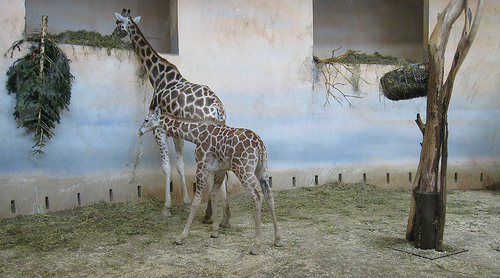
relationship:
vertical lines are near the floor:
[8, 168, 479, 217] [0, 190, 500, 278]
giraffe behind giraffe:
[137, 100, 287, 255] [110, 7, 233, 228]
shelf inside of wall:
[22, 22, 184, 62] [5, 11, 497, 200]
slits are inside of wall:
[8, 149, 498, 213] [2, 7, 490, 230]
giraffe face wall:
[110, 7, 233, 228] [1, 3, 306, 195]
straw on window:
[312, 50, 384, 108] [312, 6, 430, 66]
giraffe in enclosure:
[110, 7, 233, 228] [2, 1, 494, 275]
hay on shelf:
[28, 28, 137, 56] [21, 8, 181, 60]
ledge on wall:
[313, 34, 423, 68] [272, 4, 499, 187]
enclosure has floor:
[2, 1, 494, 275] [33, 194, 498, 274]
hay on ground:
[68, 243, 122, 263] [53, 215, 143, 264]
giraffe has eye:
[137, 100, 287, 255] [146, 119, 153, 124]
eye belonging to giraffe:
[142, 117, 150, 123] [137, 100, 287, 255]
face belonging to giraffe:
[137, 110, 156, 133] [137, 100, 287, 255]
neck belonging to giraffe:
[126, 17, 178, 85] [110, 7, 233, 228]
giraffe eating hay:
[110, 7, 233, 228] [26, 27, 139, 61]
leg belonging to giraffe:
[153, 128, 172, 218] [110, 7, 233, 228]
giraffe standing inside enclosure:
[137, 100, 287, 255] [0, 1, 499, 277]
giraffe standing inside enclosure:
[110, 7, 233, 228] [0, 1, 499, 277]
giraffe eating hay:
[110, 7, 233, 228] [28, 28, 137, 56]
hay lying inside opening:
[28, 28, 137, 56] [24, 1, 177, 55]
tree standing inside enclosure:
[402, 4, 482, 247] [0, 1, 499, 277]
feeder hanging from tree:
[378, 68, 428, 102] [402, 4, 482, 247]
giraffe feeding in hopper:
[110, 7, 233, 228] [24, 0, 178, 54]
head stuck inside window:
[107, 6, 132, 41] [23, 0, 178, 55]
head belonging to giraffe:
[107, 6, 132, 41] [110, 7, 233, 228]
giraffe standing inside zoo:
[110, 7, 233, 228] [2, 0, 484, 274]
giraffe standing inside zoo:
[137, 100, 287, 255] [2, 0, 484, 274]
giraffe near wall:
[137, 100, 287, 255] [75, 55, 138, 195]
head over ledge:
[111, 7, 142, 40] [58, 32, 158, 70]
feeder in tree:
[378, 65, 429, 98] [389, 2, 481, 261]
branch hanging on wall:
[4, 9, 77, 161] [79, 49, 128, 194]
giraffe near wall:
[137, 100, 287, 255] [218, 20, 297, 134]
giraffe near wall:
[104, 6, 245, 242] [218, 20, 297, 134]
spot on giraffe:
[242, 131, 253, 152] [130, 96, 290, 248]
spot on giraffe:
[231, 144, 248, 160] [116, 104, 290, 253]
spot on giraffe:
[226, 150, 241, 170] [137, 100, 287, 255]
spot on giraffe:
[242, 161, 252, 179] [125, 98, 290, 258]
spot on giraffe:
[168, 117, 179, 131] [122, 103, 278, 243]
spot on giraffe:
[188, 118, 196, 133] [137, 100, 287, 255]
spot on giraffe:
[194, 90, 210, 110] [109, 3, 237, 242]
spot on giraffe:
[176, 85, 186, 105] [104, 6, 245, 242]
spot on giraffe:
[147, 62, 159, 81] [110, 7, 233, 228]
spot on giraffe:
[136, 35, 154, 57] [104, 6, 245, 242]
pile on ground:
[283, 170, 409, 221] [278, 210, 399, 276]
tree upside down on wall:
[6, 13, 85, 157] [76, 58, 122, 188]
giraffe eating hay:
[110, 7, 233, 228] [52, 28, 132, 49]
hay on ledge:
[52, 28, 132, 49] [55, 41, 218, 62]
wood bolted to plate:
[405, 188, 445, 256] [385, 232, 472, 264]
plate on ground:
[385, 232, 472, 264] [325, 227, 480, 262]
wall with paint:
[39, 26, 442, 190] [220, 75, 370, 220]